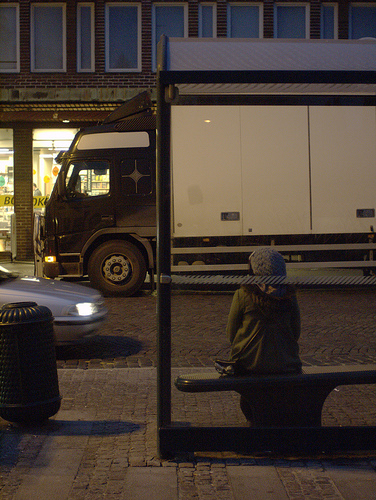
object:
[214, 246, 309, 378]
woman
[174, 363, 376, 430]
bench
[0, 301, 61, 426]
trash can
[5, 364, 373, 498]
sidewalk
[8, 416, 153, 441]
shadow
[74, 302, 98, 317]
headlight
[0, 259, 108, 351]
car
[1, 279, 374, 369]
street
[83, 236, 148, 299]
front tire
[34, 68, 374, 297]
truck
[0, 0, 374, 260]
building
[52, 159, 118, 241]
door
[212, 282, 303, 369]
coat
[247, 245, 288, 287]
hat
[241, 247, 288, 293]
head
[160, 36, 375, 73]
canopy top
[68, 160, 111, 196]
window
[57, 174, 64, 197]
mirror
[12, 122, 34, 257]
brick column